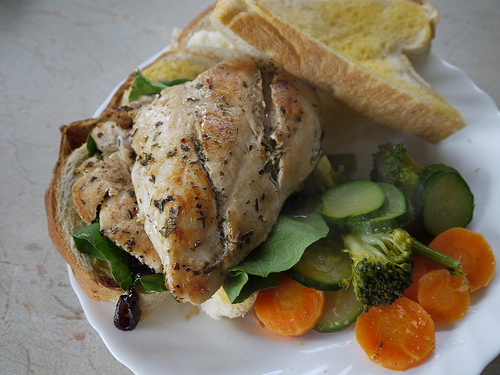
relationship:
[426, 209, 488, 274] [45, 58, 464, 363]
carrot on plate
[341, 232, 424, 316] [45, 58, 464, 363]
broccoli on plate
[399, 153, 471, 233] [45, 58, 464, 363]
cucumber on plate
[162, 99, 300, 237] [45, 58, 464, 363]
breast on plate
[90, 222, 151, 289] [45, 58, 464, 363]
zucchini on plate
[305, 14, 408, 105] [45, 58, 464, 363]
toast on plate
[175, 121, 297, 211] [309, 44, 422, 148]
chicken on bread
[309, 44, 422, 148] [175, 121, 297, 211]
bread beneath chicken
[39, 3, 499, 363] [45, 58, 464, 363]
food on plate